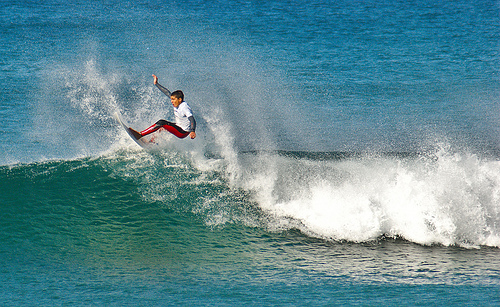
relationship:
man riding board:
[125, 74, 197, 145] [114, 110, 164, 158]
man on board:
[125, 74, 197, 145] [106, 80, 168, 172]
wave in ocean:
[2, 139, 499, 249] [1, 3, 498, 303]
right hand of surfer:
[148, 71, 166, 95] [117, 58, 216, 167]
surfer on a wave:
[108, 75, 212, 164] [6, 125, 435, 274]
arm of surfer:
[182, 107, 199, 139] [128, 68, 202, 150]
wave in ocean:
[0, 0, 499, 306] [9, 4, 489, 269]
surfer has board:
[126, 72, 198, 143] [114, 110, 164, 158]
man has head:
[125, 74, 197, 145] [168, 83, 185, 107]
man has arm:
[125, 68, 222, 155] [152, 70, 177, 101]